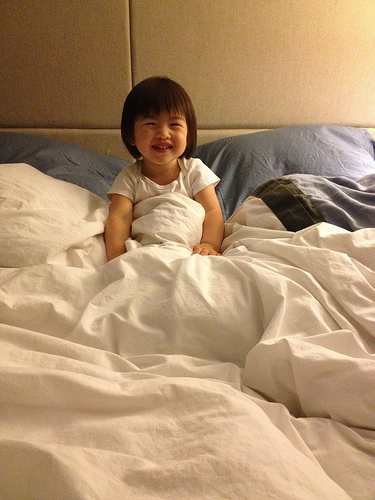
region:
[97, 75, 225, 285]
baby is posing for photograph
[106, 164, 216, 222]
baby wearing white color t-shirt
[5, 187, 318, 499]
white color blanket in the mattress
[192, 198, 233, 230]
elbow of the baby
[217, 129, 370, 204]
blue color covered pillow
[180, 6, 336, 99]
white color wall tiles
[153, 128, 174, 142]
nose of the baby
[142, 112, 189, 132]
eyes of the baby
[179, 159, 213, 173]
shoulder of the baby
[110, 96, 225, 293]
a little girl in a bed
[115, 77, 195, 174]
the head of a little girl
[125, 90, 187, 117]
the bangs of a little girl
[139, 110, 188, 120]
the eyebrows of a little girl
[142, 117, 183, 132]
the eyes of a little girl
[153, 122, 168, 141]
the nose of a little girl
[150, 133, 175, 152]
the mouth of a little girl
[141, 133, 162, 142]
the cheek of a little girl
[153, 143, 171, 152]
the teeth of a little girl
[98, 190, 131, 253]
the arm of a little girl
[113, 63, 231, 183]
girl has straight hair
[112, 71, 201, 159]
girl has brown hair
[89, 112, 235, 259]
girl has white shirt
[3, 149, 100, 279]
white pillow on bed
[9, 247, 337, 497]
white sheet on bed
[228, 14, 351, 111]
tan wall behind girl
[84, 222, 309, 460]
white sheets are rumpled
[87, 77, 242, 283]
girl sits in bed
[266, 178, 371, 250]
blue and green pillowcase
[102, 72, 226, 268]
this cute child is smiling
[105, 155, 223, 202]
the cute child is dressed in a white top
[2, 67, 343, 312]
the cute child is half buried in bedsheets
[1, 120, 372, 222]
the pillowcases are blue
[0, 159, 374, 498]
the bedsheets look pretty rumpled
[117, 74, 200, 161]
the cute child has hair cut in a pageboy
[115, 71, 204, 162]
the cute child appears to be of Asian heritage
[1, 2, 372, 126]
wall behind the child is beige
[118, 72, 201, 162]
the cute child has dark brown hair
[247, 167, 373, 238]
some other part of the bedclothes are blue and green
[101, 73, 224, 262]
little girl in bed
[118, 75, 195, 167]
the girl is smiling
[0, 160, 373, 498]
the covers are white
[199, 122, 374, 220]
the pillow is blue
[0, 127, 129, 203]
the pillow is blue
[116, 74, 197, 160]
the girl has dark hair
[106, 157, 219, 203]
the shirt is white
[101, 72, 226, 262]
the girl is under the blanket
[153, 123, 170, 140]
the girl has a nose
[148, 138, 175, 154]
the girl has a mouth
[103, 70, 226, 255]
child sitting in the bed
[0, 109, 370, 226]
blue pillows behind the child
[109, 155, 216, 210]
white shirt the child is wearing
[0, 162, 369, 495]
white sheet on the bed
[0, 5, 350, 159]
wall behind the child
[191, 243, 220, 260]
hand of the child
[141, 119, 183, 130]
eyes of the child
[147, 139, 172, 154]
mouth of the child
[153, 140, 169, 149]
teeth of the child